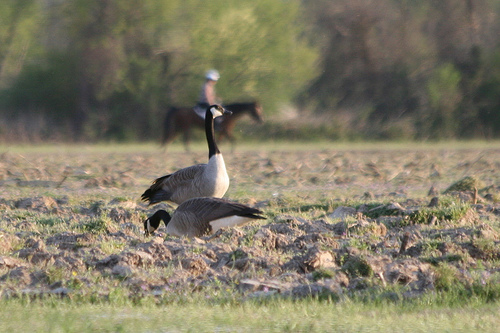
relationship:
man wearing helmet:
[198, 66, 218, 106] [202, 65, 222, 83]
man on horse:
[198, 66, 218, 106] [157, 95, 265, 139]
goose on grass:
[157, 95, 254, 250] [40, 204, 371, 329]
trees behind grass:
[36, 10, 437, 132] [57, 144, 427, 302]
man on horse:
[198, 66, 218, 106] [168, 99, 249, 139]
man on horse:
[186, 66, 236, 106] [166, 106, 291, 144]